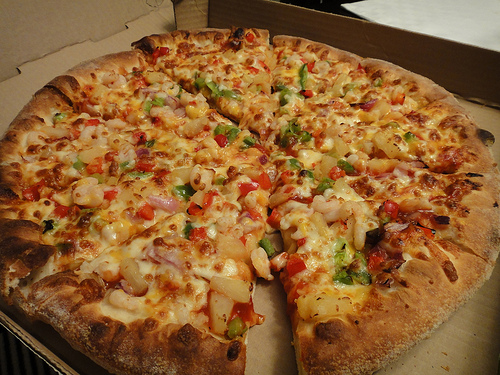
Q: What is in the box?
A: Pizza.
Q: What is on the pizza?
A: Toppings.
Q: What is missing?
A: Piece of pizza.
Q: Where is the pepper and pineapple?
A: On the pizza.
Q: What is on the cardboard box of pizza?
A: Pizza.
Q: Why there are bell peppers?
A: Topping.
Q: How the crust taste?
A: Crisp and toasted.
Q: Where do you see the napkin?
A: Next to the pizza box.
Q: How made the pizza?
A: Cook.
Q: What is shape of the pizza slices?
A: Triangular.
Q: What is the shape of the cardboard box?
A: Square.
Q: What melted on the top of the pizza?
A: Cheese.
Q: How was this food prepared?
A: Baked.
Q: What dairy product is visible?
A: Cheese.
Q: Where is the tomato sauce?
A: Under the cheese.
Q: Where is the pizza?
A: Inside a cardboard box.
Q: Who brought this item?
A: Pizza delivery person.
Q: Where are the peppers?
A: On the pizza.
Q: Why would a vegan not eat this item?
A: Because of the cheese.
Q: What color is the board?
A: Brown.